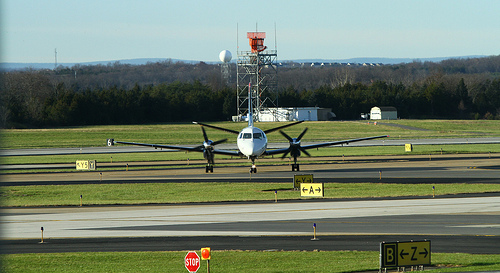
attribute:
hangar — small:
[369, 104, 399, 121]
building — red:
[245, 30, 267, 53]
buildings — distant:
[292, 54, 342, 69]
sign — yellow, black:
[299, 180, 325, 196]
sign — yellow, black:
[374, 236, 434, 270]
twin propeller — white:
[195, 127, 312, 161]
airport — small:
[0, 64, 495, 271]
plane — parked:
[108, 82, 385, 172]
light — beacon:
[30, 215, 55, 256]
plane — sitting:
[105, 119, 388, 171]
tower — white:
[211, 42, 243, 70]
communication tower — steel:
[230, 24, 284, 121]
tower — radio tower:
[232, 22, 279, 124]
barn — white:
[362, 104, 400, 121]